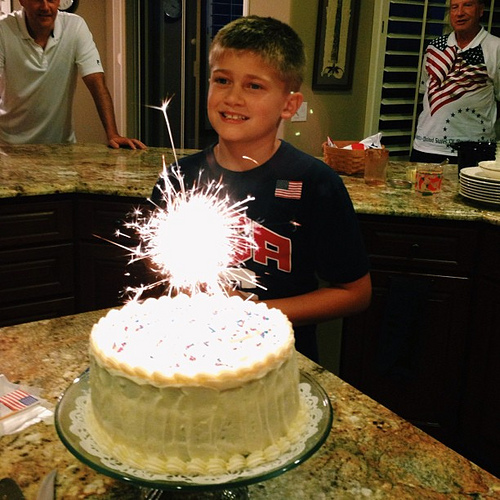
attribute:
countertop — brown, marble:
[1, 140, 500, 226]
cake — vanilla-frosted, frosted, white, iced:
[84, 291, 313, 479]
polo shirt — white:
[1, 8, 104, 145]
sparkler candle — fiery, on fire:
[88, 92, 270, 318]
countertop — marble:
[0, 297, 500, 499]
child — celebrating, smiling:
[145, 12, 372, 363]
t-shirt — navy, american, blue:
[151, 140, 367, 339]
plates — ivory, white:
[459, 164, 500, 204]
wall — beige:
[10, 1, 107, 143]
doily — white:
[69, 382, 322, 487]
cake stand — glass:
[54, 366, 334, 500]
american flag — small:
[1, 388, 41, 422]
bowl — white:
[479, 159, 500, 178]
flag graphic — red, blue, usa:
[424, 33, 490, 116]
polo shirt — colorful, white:
[411, 25, 499, 157]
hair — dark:
[207, 15, 309, 95]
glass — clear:
[414, 162, 447, 216]